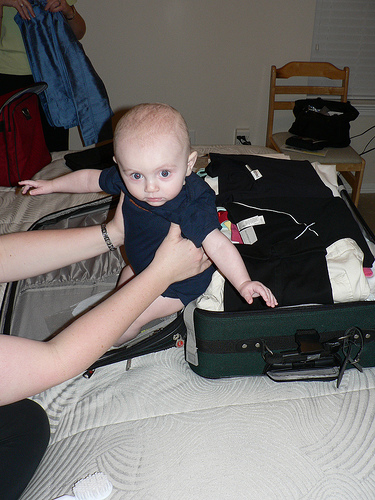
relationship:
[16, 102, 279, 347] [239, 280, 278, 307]
baby has hand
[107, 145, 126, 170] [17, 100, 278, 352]
ear on baby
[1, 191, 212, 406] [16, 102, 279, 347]
woman holding baby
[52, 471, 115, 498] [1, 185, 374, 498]
brush on bed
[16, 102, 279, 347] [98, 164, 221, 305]
baby wearing shirt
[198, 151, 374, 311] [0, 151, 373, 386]
clothes in suitcase